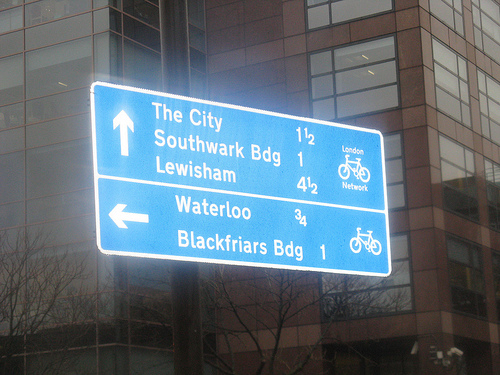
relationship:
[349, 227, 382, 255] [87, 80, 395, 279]
symbol on sign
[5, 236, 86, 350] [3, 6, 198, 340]
reflection on glass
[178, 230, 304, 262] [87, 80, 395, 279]
blackfriears bdg on sign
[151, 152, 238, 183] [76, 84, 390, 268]
word on sign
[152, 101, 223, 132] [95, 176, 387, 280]
city on sign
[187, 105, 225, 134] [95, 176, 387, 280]
word on sign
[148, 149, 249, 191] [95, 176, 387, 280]
word on sign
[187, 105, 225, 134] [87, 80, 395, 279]
word on sign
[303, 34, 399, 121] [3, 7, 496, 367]
windows on building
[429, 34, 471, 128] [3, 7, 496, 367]
windows on building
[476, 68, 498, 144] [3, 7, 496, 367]
windows on building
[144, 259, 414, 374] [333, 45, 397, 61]
tree reflecting in window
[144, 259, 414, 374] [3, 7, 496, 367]
tree in front of building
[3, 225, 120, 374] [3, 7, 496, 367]
tree in front of building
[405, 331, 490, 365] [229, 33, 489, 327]
cameras on building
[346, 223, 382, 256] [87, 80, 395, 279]
symbol on sign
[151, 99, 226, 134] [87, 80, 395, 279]
city on sign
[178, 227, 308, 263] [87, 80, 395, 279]
blackfriears bdg on sign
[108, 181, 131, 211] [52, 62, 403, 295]
light reflecting sign